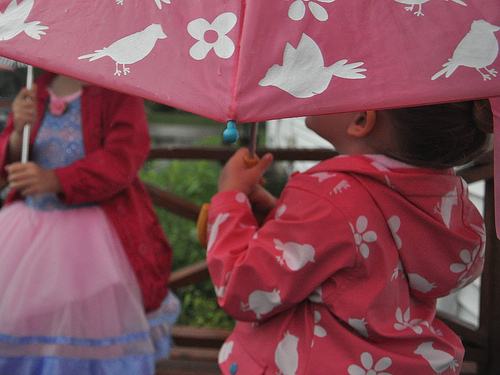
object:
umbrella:
[0, 0, 497, 247]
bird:
[76, 23, 167, 76]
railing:
[149, 145, 477, 161]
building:
[263, 117, 500, 330]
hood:
[301, 154, 488, 300]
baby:
[0, 80, 153, 323]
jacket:
[206, 155, 485, 374]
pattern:
[185, 12, 238, 62]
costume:
[0, 85, 180, 375]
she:
[0, 73, 181, 374]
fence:
[131, 146, 499, 349]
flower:
[187, 12, 239, 62]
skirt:
[0, 200, 182, 375]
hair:
[366, 98, 495, 170]